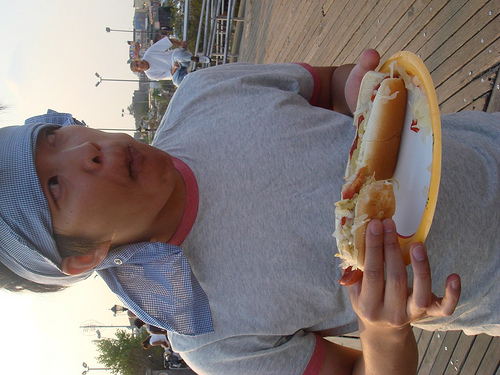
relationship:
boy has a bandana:
[1, 48, 498, 374] [0, 109, 215, 336]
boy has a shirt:
[1, 48, 498, 374] [148, 62, 500, 375]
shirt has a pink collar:
[148, 62, 500, 375] [171, 158, 199, 245]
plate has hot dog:
[374, 50, 442, 266] [341, 171, 366, 199]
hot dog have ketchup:
[341, 171, 366, 199] [349, 74, 391, 165]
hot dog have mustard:
[341, 171, 366, 199] [346, 113, 368, 179]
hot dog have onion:
[341, 171, 366, 199] [332, 61, 427, 271]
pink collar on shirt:
[171, 158, 199, 245] [148, 62, 500, 375]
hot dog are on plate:
[341, 171, 366, 199] [374, 50, 442, 266]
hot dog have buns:
[341, 171, 366, 199] [334, 69, 406, 270]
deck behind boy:
[237, 0, 499, 374] [1, 48, 498, 374]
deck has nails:
[237, 0, 499, 374] [463, 9, 497, 104]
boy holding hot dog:
[1, 48, 498, 374] [341, 171, 366, 199]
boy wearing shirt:
[1, 48, 498, 374] [148, 62, 500, 375]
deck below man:
[237, 0, 499, 374] [130, 35, 211, 90]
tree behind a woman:
[91, 329, 166, 374] [143, 333, 172, 351]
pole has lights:
[99, 78, 169, 82] [94, 71, 101, 87]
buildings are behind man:
[129, 0, 174, 145] [130, 35, 211, 90]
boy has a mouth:
[1, 48, 498, 374] [122, 144, 147, 182]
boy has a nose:
[1, 48, 498, 374] [49, 140, 103, 174]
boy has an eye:
[1, 48, 498, 374] [45, 124, 57, 149]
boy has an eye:
[1, 48, 498, 374] [47, 175, 60, 200]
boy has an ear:
[1, 48, 498, 374] [61, 239, 110, 277]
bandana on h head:
[0, 109, 215, 336] [35, 125, 174, 251]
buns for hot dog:
[331, 72, 411, 274] [341, 171, 366, 199]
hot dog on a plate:
[334, 171, 366, 194] [374, 50, 442, 266]